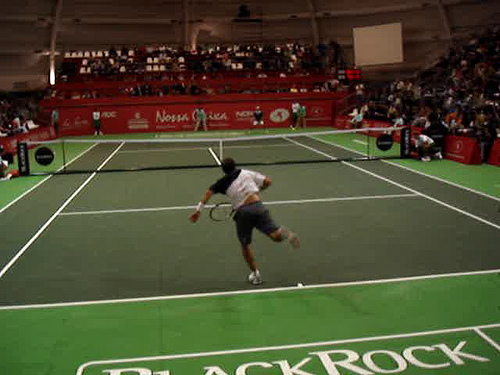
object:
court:
[0, 128, 500, 375]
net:
[28, 127, 402, 177]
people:
[192, 106, 209, 132]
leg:
[234, 218, 262, 285]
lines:
[0, 269, 500, 309]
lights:
[69, 15, 83, 25]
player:
[247, 104, 269, 133]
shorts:
[253, 120, 264, 125]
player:
[188, 156, 303, 283]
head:
[219, 157, 239, 175]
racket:
[209, 202, 234, 222]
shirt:
[208, 168, 269, 210]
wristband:
[195, 202, 205, 212]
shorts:
[232, 200, 281, 245]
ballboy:
[412, 133, 442, 162]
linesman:
[292, 104, 308, 131]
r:
[308, 349, 370, 375]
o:
[362, 350, 406, 375]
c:
[402, 345, 450, 369]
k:
[431, 341, 491, 365]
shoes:
[244, 274, 263, 285]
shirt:
[415, 134, 434, 147]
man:
[349, 109, 363, 133]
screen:
[353, 22, 403, 66]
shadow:
[195, 29, 212, 44]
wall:
[56, 23, 185, 48]